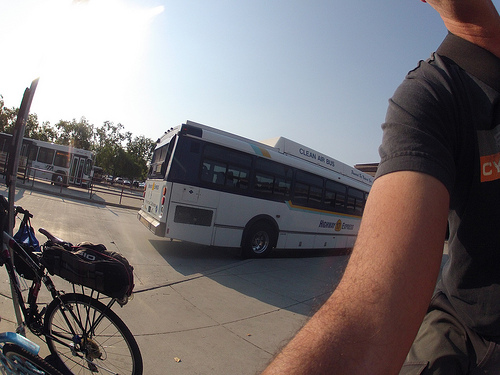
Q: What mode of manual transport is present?
A: Bicycle.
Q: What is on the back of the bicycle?
A: Backpack.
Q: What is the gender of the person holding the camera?
A: Male.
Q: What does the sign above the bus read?
A: "Clean Air Bus".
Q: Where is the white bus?
A: Behind the man.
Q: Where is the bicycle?
A: Left of man.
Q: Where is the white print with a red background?
A: Man's shirt.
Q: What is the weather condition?
A: Clear and sunny.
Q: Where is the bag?
A: On the bicycle.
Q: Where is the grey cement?
A: On the ground.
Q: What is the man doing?
A: Taking a photo of himself.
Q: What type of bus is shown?
A: A passenger bus.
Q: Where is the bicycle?
A: Leaning on a sign.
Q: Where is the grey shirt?
A: On the man.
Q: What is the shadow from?
A: A bus.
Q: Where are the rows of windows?
A: On the bus.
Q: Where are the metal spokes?
A: On the bicycle tire.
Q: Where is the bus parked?
A: On the curb.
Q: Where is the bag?
A: On the back of the bicycle.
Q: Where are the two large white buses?
A: Parked in a lot.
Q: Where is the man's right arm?
A: Reaching toward the camera.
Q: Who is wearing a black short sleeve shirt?
A: The man.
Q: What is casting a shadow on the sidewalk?
A: The white bus.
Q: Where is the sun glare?
A: Over the blue sky.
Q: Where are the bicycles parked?
A: By a street sign.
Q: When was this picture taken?
A: During the day.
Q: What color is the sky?
A: Blue.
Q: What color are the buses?
A: White.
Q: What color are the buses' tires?
A: Black.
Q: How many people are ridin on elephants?
A: Zero.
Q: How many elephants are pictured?
A: Zero.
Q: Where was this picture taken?
A: On the street.